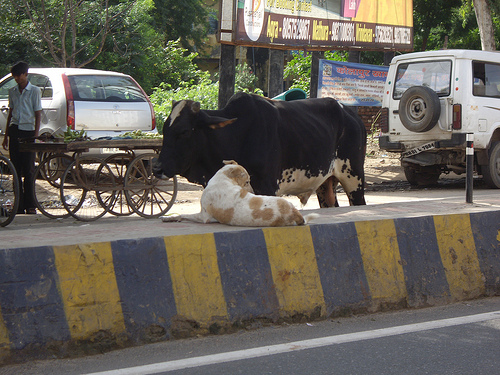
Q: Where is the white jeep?
A: Right.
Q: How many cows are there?
A: One.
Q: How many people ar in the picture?
A: One.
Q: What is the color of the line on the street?
A: White.